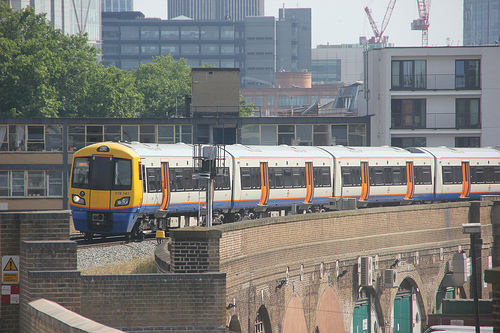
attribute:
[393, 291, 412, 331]
door — green, Dutch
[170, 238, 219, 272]
wall — red, brick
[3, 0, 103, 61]
building — tall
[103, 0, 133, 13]
building — tall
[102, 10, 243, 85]
building — tall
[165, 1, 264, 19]
building — tall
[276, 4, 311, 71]
building — tall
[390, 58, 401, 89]
window — large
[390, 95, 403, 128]
window — large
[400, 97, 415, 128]
window — large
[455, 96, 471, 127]
window — large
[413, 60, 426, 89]
window — large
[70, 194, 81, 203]
light — on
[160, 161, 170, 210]
door — orange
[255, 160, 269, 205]
door — orange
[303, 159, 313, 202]
door — orange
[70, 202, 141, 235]
paint — blue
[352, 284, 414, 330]
doors — green, closed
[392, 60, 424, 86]
sliding door — glass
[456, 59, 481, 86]
sliding door — glass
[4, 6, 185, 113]
treetops — green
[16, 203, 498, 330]
railway — raised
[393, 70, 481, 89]
railing — black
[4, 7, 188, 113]
trees — lush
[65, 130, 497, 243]
train — white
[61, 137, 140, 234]
front — yellow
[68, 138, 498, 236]
train — long